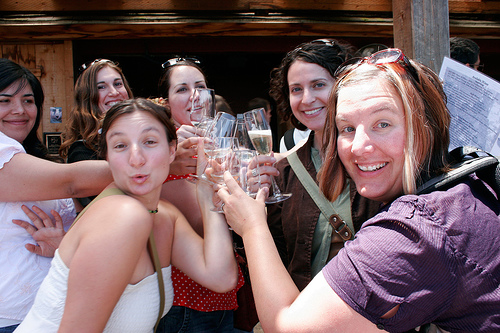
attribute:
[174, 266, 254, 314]
polka dots — red, white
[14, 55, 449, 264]
girls — toasting, posing, smiling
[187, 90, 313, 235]
glasses — toasting, held, many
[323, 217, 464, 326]
sleeve — purple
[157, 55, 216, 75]
sunglasses — black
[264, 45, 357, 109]
hair — curly, black, dark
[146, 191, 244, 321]
shirt — polka dot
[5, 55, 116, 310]
female — waving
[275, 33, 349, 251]
woman — smiling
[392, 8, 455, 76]
beam — wood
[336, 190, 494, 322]
shirt — purple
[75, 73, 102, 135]
hair — brown, blonde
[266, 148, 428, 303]
jacket — brown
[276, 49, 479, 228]
women — smiling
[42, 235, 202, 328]
top — white